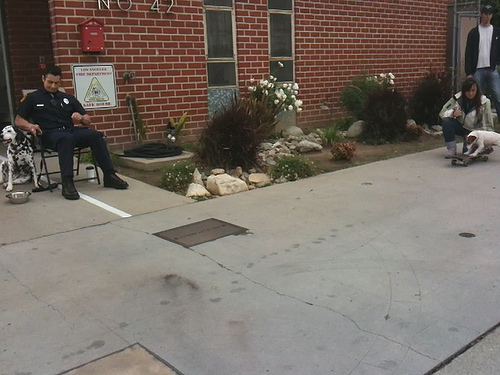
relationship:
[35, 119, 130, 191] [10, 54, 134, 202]
pants on man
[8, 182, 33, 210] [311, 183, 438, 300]
dog bowl on ground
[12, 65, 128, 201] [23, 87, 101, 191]
cop sitting in chair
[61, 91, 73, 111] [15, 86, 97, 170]
badge on shirt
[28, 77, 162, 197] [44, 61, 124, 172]
shirt on man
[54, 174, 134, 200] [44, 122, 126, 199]
shoes on feet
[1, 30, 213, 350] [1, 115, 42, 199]
cop by dog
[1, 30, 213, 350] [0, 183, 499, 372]
cop on ground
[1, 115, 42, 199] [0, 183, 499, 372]
dog on ground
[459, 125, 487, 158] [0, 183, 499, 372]
dog on ground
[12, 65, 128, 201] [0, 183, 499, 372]
cop on ground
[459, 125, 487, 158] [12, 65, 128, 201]
dog by cop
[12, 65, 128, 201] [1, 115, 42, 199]
cop by dog